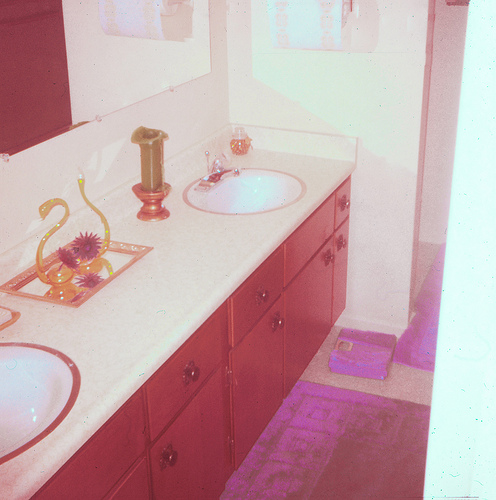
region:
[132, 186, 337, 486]
Brown cabinets under the counter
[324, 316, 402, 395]
Square purple box on the floor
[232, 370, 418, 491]
Purple rug on the floor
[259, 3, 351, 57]
White towels hanging from the wall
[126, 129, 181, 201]
A melted olive green candle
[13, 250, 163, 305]
A shiny silver tray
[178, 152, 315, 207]
White sink with a silver border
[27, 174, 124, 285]
Gold decoration with purple flowers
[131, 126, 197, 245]
The candle has a brown base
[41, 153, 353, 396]
The counter is white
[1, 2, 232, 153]
a wall mirror reflecting the door and paper towels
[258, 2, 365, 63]
a roll of paper towels on the wall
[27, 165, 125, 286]
two flowers on glass birds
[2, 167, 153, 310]
two glass birds on a vanity mirror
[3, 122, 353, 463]
bathroom counter with two sinks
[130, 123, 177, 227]
a candle on its pedestal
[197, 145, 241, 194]
a chrome bathroom faucet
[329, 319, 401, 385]
one square scale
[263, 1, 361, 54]
pink motif on the paper towel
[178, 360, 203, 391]
a metal door knob on the drawer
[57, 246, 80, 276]
a small red flower in a bathroom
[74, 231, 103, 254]
a small red flower in a bathroom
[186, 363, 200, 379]
a small red knob on a drawer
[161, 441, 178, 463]
a small red knob on a drawer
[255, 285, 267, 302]
a small red knob on a drawer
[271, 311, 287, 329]
a small red knob on a drawer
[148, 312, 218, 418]
a red drawer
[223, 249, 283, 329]
a red drawer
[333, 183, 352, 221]
a red drawer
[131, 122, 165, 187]
a brown candle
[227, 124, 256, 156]
small glass jar of bath lotion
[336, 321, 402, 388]
square pink bathroom scale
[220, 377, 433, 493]
pink bathroom throw rug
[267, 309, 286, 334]
small mauve metal cabinet handle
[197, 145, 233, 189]
elegant glass sink faucet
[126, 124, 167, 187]
large brown used candle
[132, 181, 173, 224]
dark brown decorative candle holder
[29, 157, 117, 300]
artistic crystal decorative dragon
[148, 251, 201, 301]
plain white bathroom counter top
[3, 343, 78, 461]
white sink basin with deep maroon trim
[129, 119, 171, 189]
a partially burnt candle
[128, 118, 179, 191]
the candle is green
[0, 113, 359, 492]
a two sink vanity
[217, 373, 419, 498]
a rug on the bathroom floor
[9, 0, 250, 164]
a mirror on the wall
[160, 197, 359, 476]
knobs on the doors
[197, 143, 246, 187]
the sink faucet is chrome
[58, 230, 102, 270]
daisies on a decoration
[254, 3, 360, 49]
paper towels on the wall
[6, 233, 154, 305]
a tray on the sink top